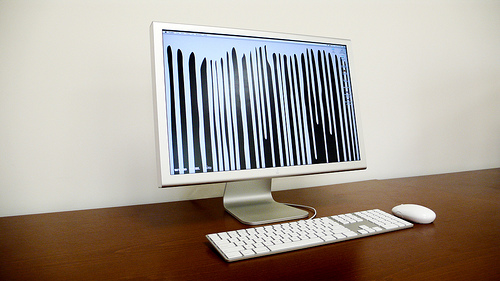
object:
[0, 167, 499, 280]
desk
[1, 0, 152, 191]
wall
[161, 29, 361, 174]
image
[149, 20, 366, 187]
screen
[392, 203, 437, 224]
mouse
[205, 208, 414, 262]
keyboard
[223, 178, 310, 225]
stand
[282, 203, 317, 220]
cord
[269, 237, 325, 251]
space bar key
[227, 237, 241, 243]
computer key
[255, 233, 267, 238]
computer key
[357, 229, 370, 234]
computer key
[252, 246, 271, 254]
computer key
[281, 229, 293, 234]
computer key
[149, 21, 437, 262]
computer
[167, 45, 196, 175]
lines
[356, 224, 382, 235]
four keys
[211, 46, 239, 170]
lines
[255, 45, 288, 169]
lines